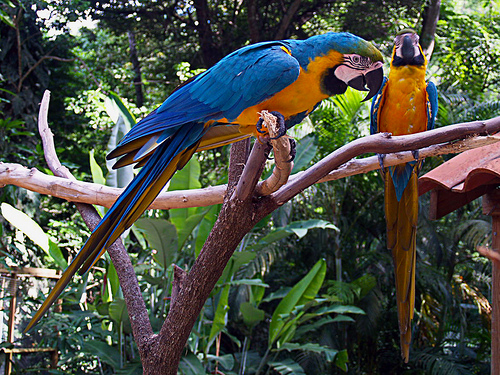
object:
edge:
[125, 257, 140, 306]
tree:
[86, 0, 428, 163]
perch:
[0, 124, 500, 211]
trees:
[0, 85, 370, 375]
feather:
[368, 81, 437, 370]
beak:
[331, 61, 384, 103]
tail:
[382, 155, 419, 364]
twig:
[373, 150, 390, 174]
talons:
[251, 108, 295, 162]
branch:
[0, 88, 500, 375]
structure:
[0, 265, 103, 375]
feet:
[254, 110, 296, 163]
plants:
[0, 0, 499, 375]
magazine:
[0, 0, 500, 375]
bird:
[21, 31, 383, 335]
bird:
[370, 28, 439, 370]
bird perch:
[0, 0, 500, 375]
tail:
[22, 119, 205, 333]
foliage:
[0, 39, 500, 375]